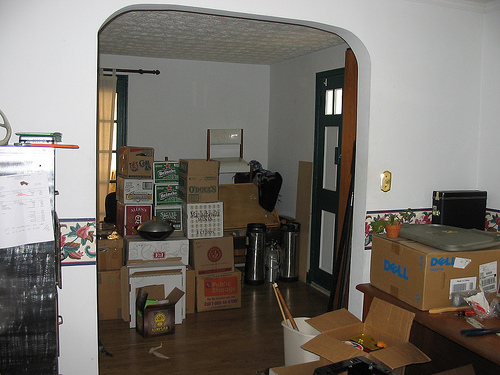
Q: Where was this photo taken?
A: House.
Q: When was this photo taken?
A: Daytime.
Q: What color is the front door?
A: Black.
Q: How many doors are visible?
A: One.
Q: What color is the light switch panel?
A: Yellow.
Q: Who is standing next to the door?
A: No one.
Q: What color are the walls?
A: White.